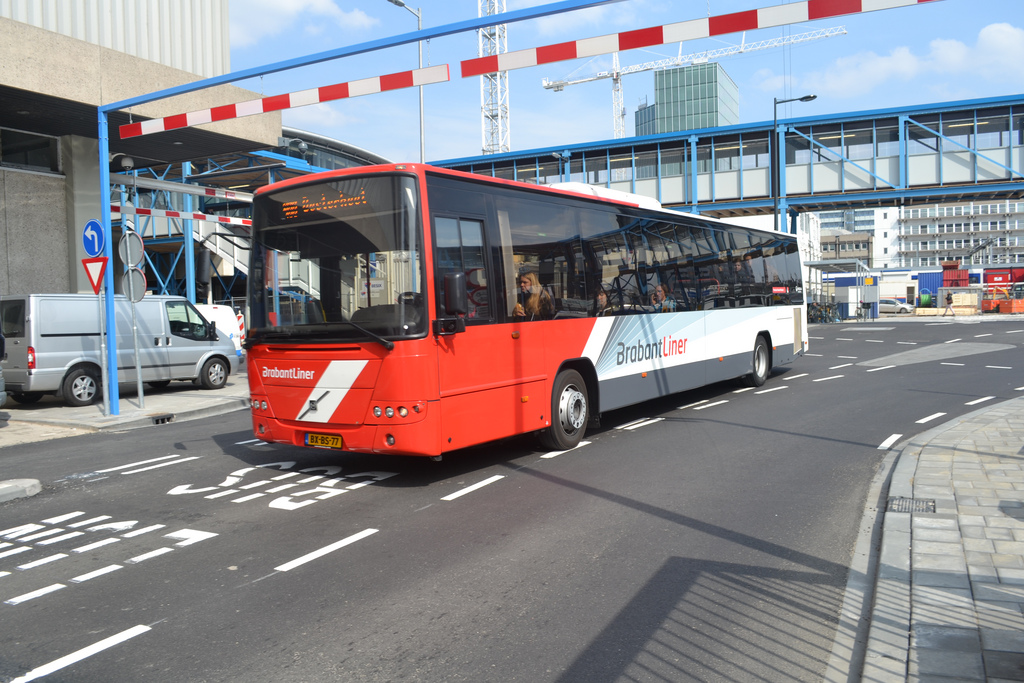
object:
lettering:
[259, 365, 315, 381]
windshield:
[247, 175, 431, 332]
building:
[414, 68, 1021, 318]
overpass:
[451, 94, 1022, 208]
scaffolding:
[119, 151, 332, 304]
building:
[649, 62, 742, 139]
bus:
[239, 162, 804, 461]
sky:
[223, 0, 1021, 114]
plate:
[302, 432, 341, 449]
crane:
[542, 24, 846, 93]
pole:
[98, 108, 122, 416]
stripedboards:
[121, 1, 943, 142]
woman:
[512, 271, 553, 322]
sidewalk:
[866, 400, 1020, 680]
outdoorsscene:
[6, 5, 1013, 680]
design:
[294, 357, 372, 424]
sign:
[76, 219, 109, 259]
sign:
[76, 254, 115, 296]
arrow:
[80, 218, 97, 257]